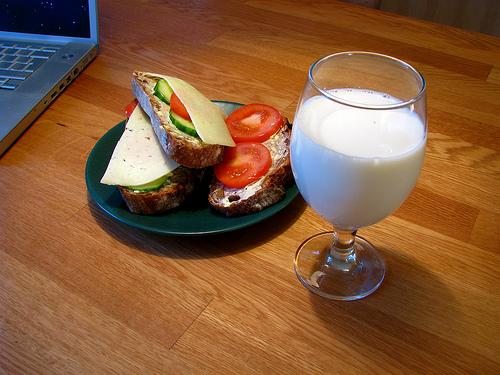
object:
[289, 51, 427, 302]
glass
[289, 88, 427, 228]
milk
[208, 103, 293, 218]
toast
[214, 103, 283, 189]
tomato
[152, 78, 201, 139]
cucumber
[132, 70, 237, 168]
toast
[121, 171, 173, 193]
cucumber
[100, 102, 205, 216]
toast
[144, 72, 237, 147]
cheese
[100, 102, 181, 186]
cheese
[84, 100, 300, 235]
saucer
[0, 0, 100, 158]
laptop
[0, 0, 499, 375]
table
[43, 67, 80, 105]
ports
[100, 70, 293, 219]
food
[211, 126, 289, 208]
butter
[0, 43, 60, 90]
keys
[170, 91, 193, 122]
tomato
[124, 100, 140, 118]
tomato